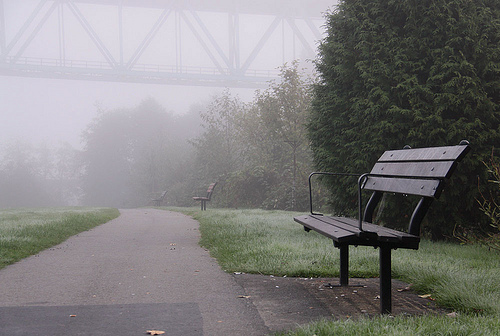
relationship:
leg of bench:
[338, 245, 351, 285] [296, 139, 473, 314]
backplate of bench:
[362, 146, 467, 200] [296, 139, 473, 314]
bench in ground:
[296, 139, 473, 314] [2, 206, 499, 332]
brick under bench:
[302, 280, 437, 321] [296, 139, 473, 314]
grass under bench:
[141, 205, 499, 335] [153, 191, 167, 205]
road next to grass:
[3, 205, 272, 333] [141, 205, 499, 335]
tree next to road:
[256, 59, 322, 215] [3, 205, 272, 333]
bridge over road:
[3, 1, 341, 85] [3, 205, 272, 333]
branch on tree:
[263, 111, 298, 153] [256, 59, 322, 215]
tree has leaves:
[256, 59, 322, 215] [280, 69, 302, 83]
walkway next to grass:
[3, 205, 272, 333] [141, 205, 499, 335]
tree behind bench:
[256, 59, 322, 215] [194, 178, 221, 210]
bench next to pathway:
[296, 139, 473, 314] [3, 205, 272, 333]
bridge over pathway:
[3, 1, 341, 85] [3, 205, 272, 333]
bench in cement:
[296, 139, 473, 314] [233, 270, 457, 331]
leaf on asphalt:
[148, 328, 161, 335] [3, 205, 272, 333]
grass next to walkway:
[141, 205, 499, 335] [3, 205, 272, 333]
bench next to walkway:
[194, 178, 221, 210] [3, 205, 272, 333]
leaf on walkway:
[148, 328, 161, 335] [3, 205, 272, 333]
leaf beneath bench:
[415, 293, 435, 299] [296, 139, 473, 314]